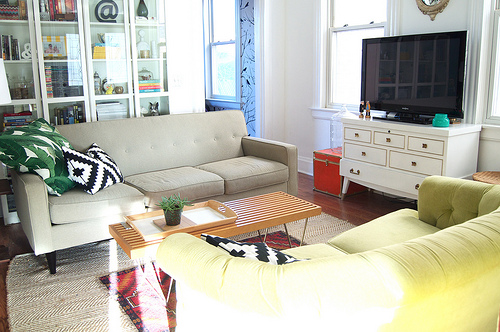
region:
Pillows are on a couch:
[0, 102, 300, 275]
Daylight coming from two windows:
[200, 0, 392, 105]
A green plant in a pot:
[150, 186, 191, 226]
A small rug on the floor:
[95, 222, 307, 327]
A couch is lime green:
[145, 170, 498, 330]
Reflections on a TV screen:
[355, 25, 467, 125]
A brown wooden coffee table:
[105, 185, 321, 260]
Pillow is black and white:
[55, 135, 125, 196]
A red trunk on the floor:
[308, 140, 370, 200]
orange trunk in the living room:
[305, 149, 356, 195]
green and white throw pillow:
[0, 117, 86, 199]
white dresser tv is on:
[331, 117, 476, 202]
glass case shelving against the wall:
[0, 0, 182, 219]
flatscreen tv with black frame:
[356, 31, 468, 127]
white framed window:
[321, 2, 396, 107]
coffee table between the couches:
[108, 188, 324, 267]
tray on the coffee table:
[130, 194, 235, 243]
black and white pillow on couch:
[53, 148, 125, 196]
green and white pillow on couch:
[0, 113, 66, 158]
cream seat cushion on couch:
[207, 148, 279, 202]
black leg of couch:
[40, 250, 61, 266]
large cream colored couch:
[0, 116, 274, 241]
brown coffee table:
[223, 186, 319, 241]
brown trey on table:
[128, 191, 237, 238]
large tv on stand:
[352, 30, 469, 113]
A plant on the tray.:
[143, 189, 195, 224]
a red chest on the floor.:
[314, 119, 353, 197]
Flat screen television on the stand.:
[355, 7, 475, 127]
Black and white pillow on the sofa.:
[68, 149, 118, 196]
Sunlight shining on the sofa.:
[252, 214, 394, 323]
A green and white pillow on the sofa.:
[23, 124, 61, 181]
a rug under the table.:
[108, 244, 212, 323]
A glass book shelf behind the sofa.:
[15, 6, 155, 107]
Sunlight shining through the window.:
[311, 7, 383, 106]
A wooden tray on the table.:
[116, 201, 246, 246]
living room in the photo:
[16, 14, 457, 330]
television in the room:
[312, 22, 489, 119]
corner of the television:
[431, 14, 489, 65]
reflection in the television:
[364, 55, 454, 105]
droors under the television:
[329, 123, 454, 177]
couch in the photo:
[13, 87, 300, 250]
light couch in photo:
[43, 96, 277, 244]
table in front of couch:
[72, 164, 335, 302]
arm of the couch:
[241, 119, 313, 184]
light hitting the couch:
[180, 201, 465, 330]